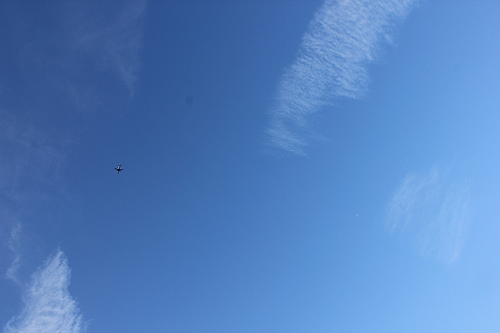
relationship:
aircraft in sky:
[115, 162, 122, 172] [1, 0, 493, 331]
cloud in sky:
[262, 0, 417, 169] [208, 91, 330, 217]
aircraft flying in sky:
[113, 163, 124, 175] [1, 0, 493, 331]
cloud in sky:
[4, 245, 91, 331] [1, 0, 493, 331]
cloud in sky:
[259, 0, 422, 160] [1, 0, 493, 331]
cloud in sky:
[279, 44, 409, 124] [173, 147, 482, 285]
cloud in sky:
[265, 1, 412, 154] [1, 0, 493, 331]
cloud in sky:
[292, 2, 378, 151] [13, 6, 434, 315]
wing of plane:
[119, 168, 125, 172] [111, 162, 126, 174]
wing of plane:
[105, 163, 117, 168] [96, 159, 139, 183]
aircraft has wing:
[113, 163, 124, 175] [114, 167, 119, 172]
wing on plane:
[116, 162, 123, 167] [110, 160, 124, 175]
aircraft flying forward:
[113, 163, 124, 175] [146, 68, 464, 209]